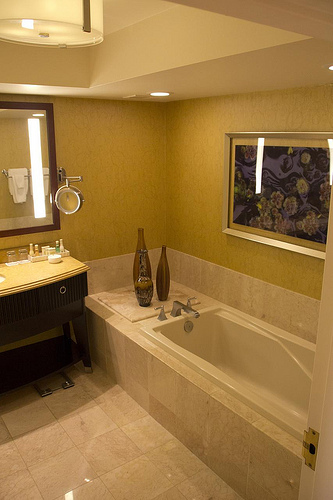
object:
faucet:
[170, 300, 200, 318]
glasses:
[6, 250, 17, 264]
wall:
[99, 112, 209, 210]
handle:
[60, 286, 67, 295]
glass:
[7, 251, 18, 263]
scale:
[34, 370, 75, 397]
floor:
[1, 421, 168, 497]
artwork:
[233, 144, 332, 244]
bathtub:
[140, 305, 315, 442]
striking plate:
[301, 427, 319, 471]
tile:
[56, 400, 118, 446]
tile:
[76, 426, 144, 477]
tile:
[144, 437, 205, 486]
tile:
[99, 391, 149, 428]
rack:
[2, 168, 31, 178]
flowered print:
[234, 144, 330, 245]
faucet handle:
[158, 309, 167, 322]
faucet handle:
[187, 300, 192, 307]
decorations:
[156, 245, 170, 301]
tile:
[42, 386, 96, 421]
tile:
[2, 399, 54, 439]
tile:
[99, 454, 174, 500]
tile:
[27, 446, 98, 499]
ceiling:
[189, 68, 255, 94]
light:
[0, 0, 104, 48]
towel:
[8, 167, 28, 203]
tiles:
[76, 369, 123, 407]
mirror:
[59, 192, 78, 212]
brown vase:
[134, 248, 153, 307]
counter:
[0, 240, 87, 303]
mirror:
[0, 109, 54, 232]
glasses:
[18, 248, 28, 261]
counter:
[0, 254, 93, 373]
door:
[298, 184, 332, 500]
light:
[150, 91, 169, 97]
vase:
[133, 228, 152, 283]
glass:
[18, 248, 28, 260]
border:
[221, 131, 333, 260]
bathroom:
[0, 0, 332, 498]